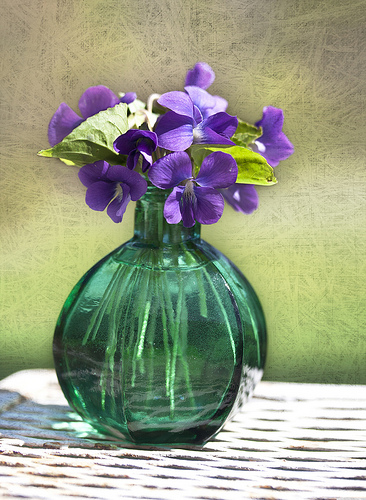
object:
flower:
[150, 86, 237, 154]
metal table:
[0, 367, 365, 499]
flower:
[180, 61, 227, 121]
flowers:
[47, 84, 138, 149]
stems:
[169, 268, 185, 422]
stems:
[196, 265, 208, 318]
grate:
[177, 433, 284, 492]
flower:
[221, 183, 259, 215]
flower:
[248, 106, 294, 170]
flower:
[146, 151, 238, 230]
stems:
[136, 258, 155, 364]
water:
[58, 241, 260, 441]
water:
[48, 235, 268, 450]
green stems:
[200, 263, 237, 368]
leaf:
[36, 100, 128, 168]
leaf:
[189, 140, 279, 187]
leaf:
[230, 118, 262, 148]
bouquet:
[35, 62, 294, 420]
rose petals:
[181, 61, 215, 96]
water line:
[110, 255, 219, 272]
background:
[0, 0, 365, 499]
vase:
[51, 183, 269, 450]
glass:
[51, 184, 268, 450]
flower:
[77, 159, 147, 224]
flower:
[112, 127, 159, 171]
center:
[182, 180, 195, 197]